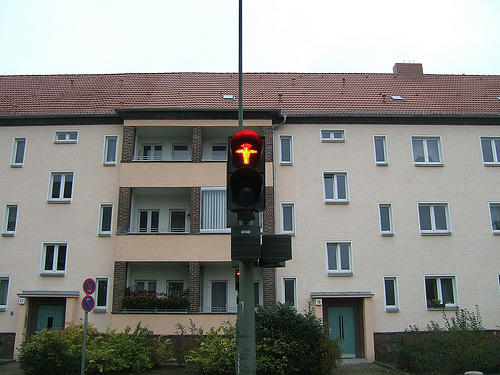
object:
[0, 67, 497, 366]
building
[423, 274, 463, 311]
window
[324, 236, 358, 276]
window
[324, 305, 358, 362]
door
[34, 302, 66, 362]
door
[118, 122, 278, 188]
balcony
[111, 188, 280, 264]
balcony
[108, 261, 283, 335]
balcony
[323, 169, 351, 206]
window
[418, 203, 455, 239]
window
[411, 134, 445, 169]
window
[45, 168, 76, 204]
window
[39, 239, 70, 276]
window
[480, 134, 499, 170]
window